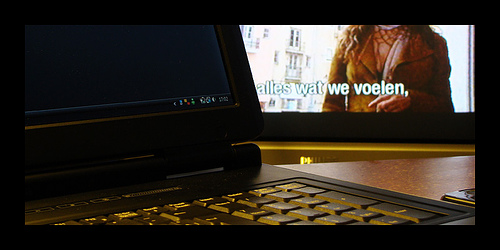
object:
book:
[439, 187, 479, 207]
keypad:
[194, 181, 447, 225]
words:
[254, 80, 404, 96]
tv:
[223, 22, 486, 143]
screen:
[0, 23, 238, 117]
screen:
[239, 23, 476, 113]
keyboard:
[25, 182, 448, 226]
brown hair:
[337, 25, 440, 64]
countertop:
[273, 156, 474, 208]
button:
[286, 208, 331, 221]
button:
[237, 196, 277, 208]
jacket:
[321, 27, 452, 114]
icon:
[173, 102, 177, 106]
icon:
[179, 100, 183, 105]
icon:
[184, 99, 191, 106]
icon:
[191, 98, 196, 105]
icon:
[200, 96, 206, 104]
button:
[232, 207, 272, 220]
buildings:
[243, 24, 341, 113]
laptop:
[24, 24, 477, 227]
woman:
[321, 22, 453, 114]